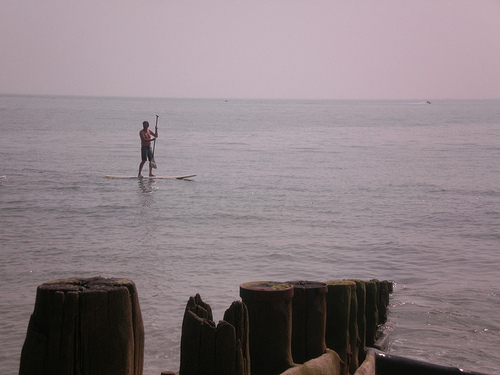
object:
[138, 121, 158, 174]
man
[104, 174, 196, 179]
surfboard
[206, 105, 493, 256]
water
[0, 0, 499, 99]
sky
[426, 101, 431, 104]
seabird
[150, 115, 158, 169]
paddle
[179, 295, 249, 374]
post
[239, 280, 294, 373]
post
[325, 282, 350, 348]
trunk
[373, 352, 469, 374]
edge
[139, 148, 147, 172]
leg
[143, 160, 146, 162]
knee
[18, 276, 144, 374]
posts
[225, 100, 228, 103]
boat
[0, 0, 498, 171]
background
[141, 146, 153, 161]
shorts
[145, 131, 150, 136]
bare chest